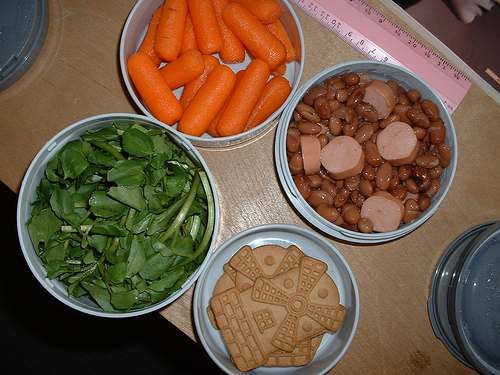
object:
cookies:
[205, 244, 346, 371]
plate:
[191, 222, 360, 374]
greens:
[44, 157, 189, 272]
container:
[17, 113, 223, 318]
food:
[286, 73, 451, 235]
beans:
[286, 73, 452, 233]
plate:
[425, 220, 499, 375]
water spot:
[410, 345, 431, 370]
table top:
[4, 2, 499, 375]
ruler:
[293, 0, 473, 116]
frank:
[321, 135, 364, 178]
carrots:
[127, 0, 295, 140]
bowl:
[118, 2, 304, 151]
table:
[0, 0, 498, 364]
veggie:
[44, 149, 189, 293]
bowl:
[15, 112, 221, 319]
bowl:
[191, 222, 363, 375]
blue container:
[427, 219, 499, 374]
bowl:
[272, 59, 458, 246]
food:
[23, 120, 217, 315]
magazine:
[397, 1, 499, 23]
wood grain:
[362, 257, 419, 334]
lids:
[429, 223, 500, 372]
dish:
[15, 112, 220, 319]